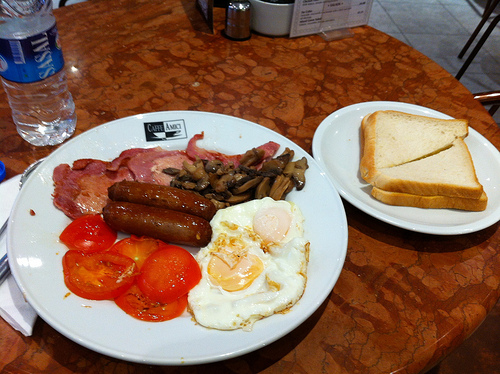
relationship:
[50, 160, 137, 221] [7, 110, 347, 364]
meat on plate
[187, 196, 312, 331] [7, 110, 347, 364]
egg on plate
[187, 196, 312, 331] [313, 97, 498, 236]
egg on plate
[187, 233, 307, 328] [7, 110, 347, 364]
egg on plate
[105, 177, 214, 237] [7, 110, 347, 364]
sausage on plate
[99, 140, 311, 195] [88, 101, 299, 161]
meat on plate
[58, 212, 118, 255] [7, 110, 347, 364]
tomato slices on plate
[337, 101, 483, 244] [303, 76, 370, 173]
bread slices on plate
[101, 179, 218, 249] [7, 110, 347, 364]
cooked sausages on plate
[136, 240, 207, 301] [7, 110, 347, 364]
tomato slices on plate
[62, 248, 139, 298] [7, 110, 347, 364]
tomato slices on plate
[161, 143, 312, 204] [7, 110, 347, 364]
mushrooms on plate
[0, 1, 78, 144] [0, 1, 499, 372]
bottle on table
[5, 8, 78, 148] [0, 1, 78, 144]
water in bottle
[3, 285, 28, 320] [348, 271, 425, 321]
napkin on table